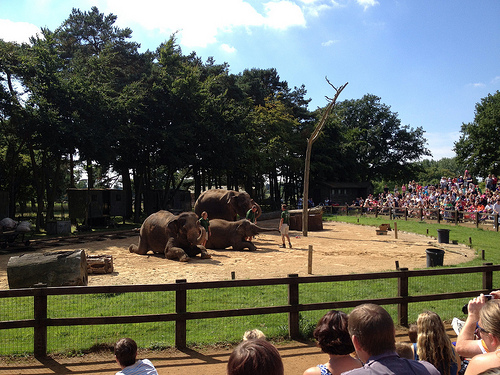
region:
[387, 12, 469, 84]
Bright blue sky above the zoo.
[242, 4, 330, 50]
A few clouds in the sky.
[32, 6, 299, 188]
Many leafy green trees.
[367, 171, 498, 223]
A crowd of people watching the elephants.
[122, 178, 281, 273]
Three elephants in the enclosure.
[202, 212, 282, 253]
Middle elephant with it's trunk extended forward.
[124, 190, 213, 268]
The elephant is kneeling down.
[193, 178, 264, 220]
The third elephant is standing.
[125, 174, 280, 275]
Three elephants being made to perform.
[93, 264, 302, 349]
A fence to keep the elephants safe.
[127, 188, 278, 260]
the elephants performing tricks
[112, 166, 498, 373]
the people in the audience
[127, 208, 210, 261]
the elephant lying down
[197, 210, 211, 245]
the person near the elephant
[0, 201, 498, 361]
the fence for the enclosure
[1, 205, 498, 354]
the grass in the enclosure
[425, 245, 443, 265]
the black bin in the enclosure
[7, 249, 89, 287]
the large wood log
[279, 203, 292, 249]
the person standing in front of the elephant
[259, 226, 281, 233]
the elephant's trunk stretched out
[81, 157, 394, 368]
people making a show with elephants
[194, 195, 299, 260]
three persons wears green shirts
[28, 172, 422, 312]
a fence in front elephants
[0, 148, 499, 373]
viewers around the elephants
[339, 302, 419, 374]
man wears a blue shirt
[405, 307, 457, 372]
woman has long hair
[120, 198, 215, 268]
person on left side of elephant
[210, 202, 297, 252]
person on front of elephant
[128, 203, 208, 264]
the elephant is kneeling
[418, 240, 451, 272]
green trash of can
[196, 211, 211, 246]
A person in green standing beside the frist elephant.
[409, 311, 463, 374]
A woman with wavy blonde and light brown hair.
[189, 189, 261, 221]
Largest elephant standing up.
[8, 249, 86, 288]
Thickest grey log on the ground.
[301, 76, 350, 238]
A tall thin tree trunk with no leaves.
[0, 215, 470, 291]
Brown dirt area where the elephants perform.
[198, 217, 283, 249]
Smallest brown elephant with extended trunk.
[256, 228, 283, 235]
Long thin middle elephant trunk.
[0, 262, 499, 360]
Close brown fence in front of people sitting.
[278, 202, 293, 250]
A man in a green shirt facing the elephants.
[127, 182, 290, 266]
a group of elephants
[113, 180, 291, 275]
three elephants on the dirt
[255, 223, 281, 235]
trunk is outstretched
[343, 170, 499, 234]
spectators in the stands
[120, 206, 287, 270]
two elephants laying on the dirt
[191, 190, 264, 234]
elephant standing on the dirt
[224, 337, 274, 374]
the back of a person's head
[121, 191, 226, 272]
person standing by the elephant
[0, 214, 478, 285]
dirt on the ground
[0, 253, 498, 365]
fence along the grass